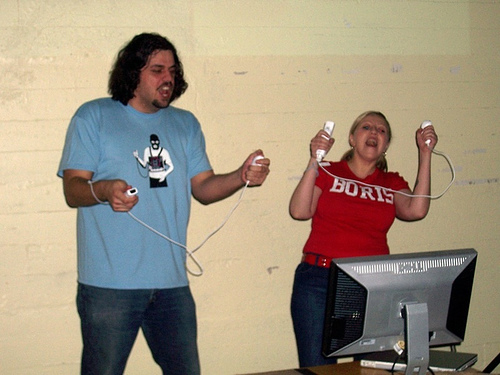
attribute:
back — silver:
[369, 272, 454, 302]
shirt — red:
[302, 160, 410, 261]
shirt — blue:
[57, 98, 215, 290]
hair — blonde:
[342, 110, 391, 174]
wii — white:
[316, 118, 335, 164]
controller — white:
[125, 186, 140, 197]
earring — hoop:
[380, 150, 388, 157]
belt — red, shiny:
[300, 251, 332, 270]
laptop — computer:
[360, 352, 479, 372]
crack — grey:
[453, 179, 500, 185]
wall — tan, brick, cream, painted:
[443, 7, 500, 194]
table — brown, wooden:
[231, 361, 486, 374]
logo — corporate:
[331, 175, 398, 204]